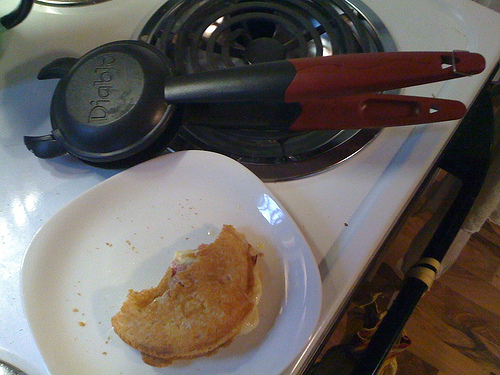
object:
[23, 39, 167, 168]
circular panel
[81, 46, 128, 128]
letters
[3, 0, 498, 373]
stove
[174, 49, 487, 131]
handle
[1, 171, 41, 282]
light reflection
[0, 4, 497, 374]
white surface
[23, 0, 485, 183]
cooker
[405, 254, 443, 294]
yellow cord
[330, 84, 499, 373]
pole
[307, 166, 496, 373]
floor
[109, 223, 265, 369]
sandwich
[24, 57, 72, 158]
curved hinges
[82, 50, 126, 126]
word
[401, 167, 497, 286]
napkin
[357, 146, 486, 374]
handle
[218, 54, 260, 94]
ground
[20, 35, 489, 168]
cooker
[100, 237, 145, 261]
bread crumbs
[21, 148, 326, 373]
plate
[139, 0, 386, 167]
coil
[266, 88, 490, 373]
oven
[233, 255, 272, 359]
filling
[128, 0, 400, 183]
burner